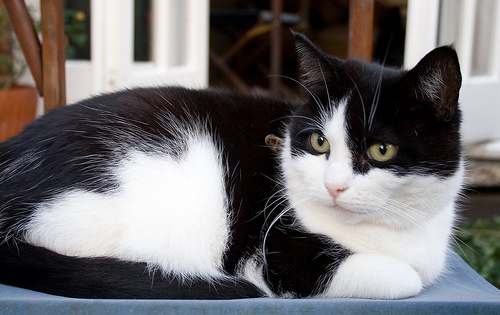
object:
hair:
[284, 150, 455, 298]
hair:
[27, 126, 232, 283]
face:
[276, 81, 461, 204]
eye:
[365, 139, 403, 162]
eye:
[295, 128, 332, 158]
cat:
[0, 29, 465, 298]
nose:
[321, 172, 350, 199]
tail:
[6, 238, 265, 300]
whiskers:
[257, 167, 322, 263]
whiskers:
[270, 63, 400, 132]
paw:
[269, 223, 426, 305]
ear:
[288, 29, 342, 92]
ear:
[408, 45, 465, 120]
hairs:
[299, 48, 323, 88]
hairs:
[422, 72, 444, 106]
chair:
[2, 240, 497, 314]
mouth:
[320, 198, 367, 221]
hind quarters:
[0, 87, 261, 298]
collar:
[261, 131, 284, 154]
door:
[69, 0, 208, 93]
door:
[406, 0, 499, 146]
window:
[132, 0, 189, 66]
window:
[441, 0, 496, 79]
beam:
[0, 0, 72, 142]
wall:
[1, 0, 211, 89]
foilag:
[454, 220, 499, 286]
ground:
[450, 141, 499, 297]